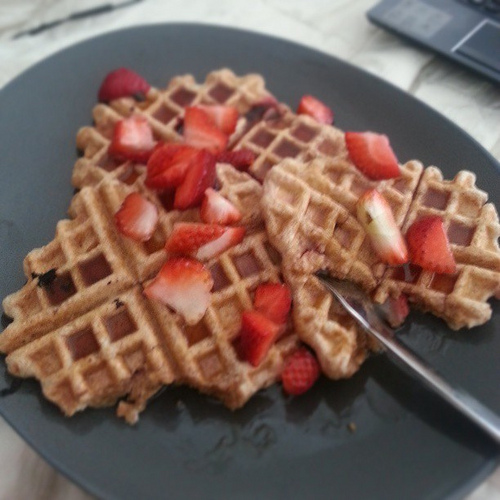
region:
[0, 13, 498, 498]
black oval plate holding food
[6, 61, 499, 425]
a mix of waffles and strawberries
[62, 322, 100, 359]
syrup in the square of the waffle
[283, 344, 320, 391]
small red slice of strawberry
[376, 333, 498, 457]
silver utensil handle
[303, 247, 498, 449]
fork sticking in a waffle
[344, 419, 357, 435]
small bit of food on the plate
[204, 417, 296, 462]
syrup smeared on the plate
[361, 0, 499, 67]
corner of a laptop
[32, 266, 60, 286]
black bit on the waffle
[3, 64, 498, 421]
waffles with bits of strawberries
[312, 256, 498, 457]
silver fork stuck into the waffle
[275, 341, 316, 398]
bit of red strawberry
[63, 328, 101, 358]
small square filled with syrup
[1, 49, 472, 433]
food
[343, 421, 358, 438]
crumb on the plate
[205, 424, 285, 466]
bit of syrup on a plate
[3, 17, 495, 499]
black oval plate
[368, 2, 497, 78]
bottom corner of a laptop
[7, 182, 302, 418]
a browned waffle piece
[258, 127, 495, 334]
a browned waffle piece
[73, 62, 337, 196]
a browned waffle piece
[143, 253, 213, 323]
a slice of red strawberry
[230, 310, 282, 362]
a slice of red strawberry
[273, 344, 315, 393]
a slice of red strawberry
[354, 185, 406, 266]
a slice of red strawberry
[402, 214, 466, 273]
a slice of red strawberry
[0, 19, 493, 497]
a dark grey plate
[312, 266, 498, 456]
a silver fork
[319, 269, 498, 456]
silver metal fork in waffle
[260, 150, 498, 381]
waffle on top of waffle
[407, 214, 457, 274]
piece of strawberry on top of waffle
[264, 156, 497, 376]
waffle under strawberry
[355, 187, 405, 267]
strawberry is white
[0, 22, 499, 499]
gray ceramic plate under waffles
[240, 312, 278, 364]
strawberry next to strawberry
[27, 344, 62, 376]
square pocket in a waffle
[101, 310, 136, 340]
syrup inside waffle pocket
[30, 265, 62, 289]
black charred area on waffle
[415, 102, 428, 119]
edge of a board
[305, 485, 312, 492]
side of a plate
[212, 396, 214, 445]
part of a plate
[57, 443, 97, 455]
edge of a tray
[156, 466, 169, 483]
side of a bowl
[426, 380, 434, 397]
part of a knife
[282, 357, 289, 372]
part of a berry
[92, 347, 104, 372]
part of a waffle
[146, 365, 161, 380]
edge of a waffle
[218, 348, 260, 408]
piece of a waffle